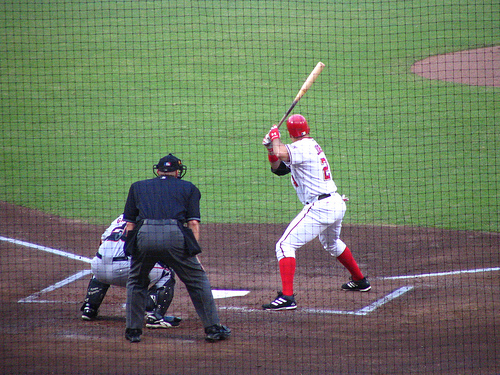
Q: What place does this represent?
A: It represents the field.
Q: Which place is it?
A: It is a field.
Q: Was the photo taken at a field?
A: Yes, it was taken in a field.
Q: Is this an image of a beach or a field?
A: It is showing a field.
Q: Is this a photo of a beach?
A: No, the picture is showing a field.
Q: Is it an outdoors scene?
A: Yes, it is outdoors.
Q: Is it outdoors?
A: Yes, it is outdoors.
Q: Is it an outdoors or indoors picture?
A: It is outdoors.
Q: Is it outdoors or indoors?
A: It is outdoors.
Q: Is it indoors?
A: No, it is outdoors.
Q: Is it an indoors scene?
A: No, it is outdoors.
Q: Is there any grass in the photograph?
A: Yes, there is grass.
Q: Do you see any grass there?
A: Yes, there is grass.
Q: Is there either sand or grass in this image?
A: Yes, there is grass.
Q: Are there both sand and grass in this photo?
A: No, there is grass but no sand.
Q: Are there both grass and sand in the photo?
A: No, there is grass but no sand.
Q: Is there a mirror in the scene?
A: No, there are no mirrors.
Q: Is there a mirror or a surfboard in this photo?
A: No, there are no mirrors or surfboards.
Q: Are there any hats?
A: Yes, there is a hat.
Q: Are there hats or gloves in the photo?
A: Yes, there is a hat.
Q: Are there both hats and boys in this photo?
A: No, there is a hat but no boys.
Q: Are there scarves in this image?
A: No, there are no scarves.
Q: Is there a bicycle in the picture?
A: No, there are no bicycles.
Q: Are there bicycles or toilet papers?
A: No, there are no bicycles or toilet papers.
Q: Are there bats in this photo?
A: Yes, there is a bat.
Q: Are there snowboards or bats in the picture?
A: Yes, there is a bat.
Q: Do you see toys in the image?
A: No, there are no toys.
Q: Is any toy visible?
A: No, there are no toys.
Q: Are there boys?
A: No, there are no boys.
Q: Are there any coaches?
A: No, there are no coaches.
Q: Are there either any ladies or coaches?
A: No, there are no coaches or ladies.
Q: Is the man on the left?
A: Yes, the man is on the left of the image.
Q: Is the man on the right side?
A: No, the man is on the left of the image.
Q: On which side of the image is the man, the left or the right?
A: The man is on the left of the image.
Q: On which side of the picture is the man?
A: The man is on the left of the image.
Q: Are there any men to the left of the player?
A: Yes, there is a man to the left of the player.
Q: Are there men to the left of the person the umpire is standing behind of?
A: Yes, there is a man to the left of the player.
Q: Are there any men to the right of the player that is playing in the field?
A: No, the man is to the left of the player.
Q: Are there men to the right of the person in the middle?
A: No, the man is to the left of the player.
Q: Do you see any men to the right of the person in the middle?
A: No, the man is to the left of the player.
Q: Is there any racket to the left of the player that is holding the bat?
A: No, there is a man to the left of the player.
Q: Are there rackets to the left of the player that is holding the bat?
A: No, there is a man to the left of the player.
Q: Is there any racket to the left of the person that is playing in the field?
A: No, there is a man to the left of the player.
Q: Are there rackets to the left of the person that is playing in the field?
A: No, there is a man to the left of the player.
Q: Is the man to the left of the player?
A: Yes, the man is to the left of the player.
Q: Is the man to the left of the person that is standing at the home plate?
A: Yes, the man is to the left of the player.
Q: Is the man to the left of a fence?
A: No, the man is to the left of the player.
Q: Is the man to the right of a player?
A: No, the man is to the left of a player.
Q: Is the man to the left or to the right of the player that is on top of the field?
A: The man is to the left of the player.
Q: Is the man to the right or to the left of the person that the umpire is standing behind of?
A: The man is to the left of the player.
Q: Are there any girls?
A: No, there are no girls.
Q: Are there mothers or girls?
A: No, there are no girls or mothers.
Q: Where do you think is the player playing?
A: The player is playing in the field.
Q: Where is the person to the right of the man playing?
A: The player is playing in the field.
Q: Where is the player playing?
A: The player is playing in the field.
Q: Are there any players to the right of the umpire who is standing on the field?
A: Yes, there is a player to the right of the umpire.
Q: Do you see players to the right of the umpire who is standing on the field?
A: Yes, there is a player to the right of the umpire.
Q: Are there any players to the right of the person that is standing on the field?
A: Yes, there is a player to the right of the umpire.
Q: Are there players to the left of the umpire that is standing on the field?
A: No, the player is to the right of the umpire.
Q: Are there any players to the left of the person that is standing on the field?
A: No, the player is to the right of the umpire.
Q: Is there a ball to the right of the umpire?
A: No, there is a player to the right of the umpire.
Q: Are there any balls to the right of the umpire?
A: No, there is a player to the right of the umpire.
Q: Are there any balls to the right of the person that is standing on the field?
A: No, there is a player to the right of the umpire.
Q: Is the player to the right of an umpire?
A: Yes, the player is to the right of an umpire.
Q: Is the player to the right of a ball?
A: No, the player is to the right of an umpire.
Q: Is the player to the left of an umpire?
A: No, the player is to the right of an umpire.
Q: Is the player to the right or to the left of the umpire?
A: The player is to the right of the umpire.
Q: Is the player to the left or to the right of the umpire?
A: The player is to the right of the umpire.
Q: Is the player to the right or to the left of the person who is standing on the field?
A: The player is to the right of the umpire.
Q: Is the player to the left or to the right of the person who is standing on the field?
A: The player is to the right of the umpire.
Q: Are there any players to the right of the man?
A: Yes, there is a player to the right of the man.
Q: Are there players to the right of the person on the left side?
A: Yes, there is a player to the right of the man.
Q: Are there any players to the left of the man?
A: No, the player is to the right of the man.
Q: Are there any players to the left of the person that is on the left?
A: No, the player is to the right of the man.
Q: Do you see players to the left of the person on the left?
A: No, the player is to the right of the man.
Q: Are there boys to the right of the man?
A: No, there is a player to the right of the man.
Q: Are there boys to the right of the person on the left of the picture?
A: No, there is a player to the right of the man.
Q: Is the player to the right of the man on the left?
A: Yes, the player is to the right of the man.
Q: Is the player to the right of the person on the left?
A: Yes, the player is to the right of the man.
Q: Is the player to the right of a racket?
A: No, the player is to the right of the man.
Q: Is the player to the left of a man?
A: No, the player is to the right of a man.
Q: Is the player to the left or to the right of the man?
A: The player is to the right of the man.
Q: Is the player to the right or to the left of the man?
A: The player is to the right of the man.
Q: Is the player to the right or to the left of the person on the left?
A: The player is to the right of the man.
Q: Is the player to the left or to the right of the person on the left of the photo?
A: The player is to the right of the man.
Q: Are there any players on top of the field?
A: Yes, there is a player on top of the field.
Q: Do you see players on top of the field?
A: Yes, there is a player on top of the field.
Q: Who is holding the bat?
A: The player is holding the bat.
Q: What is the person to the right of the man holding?
A: The player is holding the bat.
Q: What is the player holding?
A: The player is holding the bat.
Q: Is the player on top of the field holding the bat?
A: Yes, the player is holding the bat.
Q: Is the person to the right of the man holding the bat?
A: Yes, the player is holding the bat.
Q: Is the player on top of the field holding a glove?
A: No, the player is holding the bat.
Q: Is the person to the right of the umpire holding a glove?
A: No, the player is holding the bat.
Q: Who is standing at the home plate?
A: The player is standing at the home plate.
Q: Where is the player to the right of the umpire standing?
A: The player is standing at the home plate.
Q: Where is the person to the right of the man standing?
A: The player is standing at the home plate.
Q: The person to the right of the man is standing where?
A: The player is standing at the home plate.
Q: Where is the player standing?
A: The player is standing at the home plate.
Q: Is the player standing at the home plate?
A: Yes, the player is standing at the home plate.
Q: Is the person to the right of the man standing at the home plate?
A: Yes, the player is standing at the home plate.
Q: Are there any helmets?
A: Yes, there is a helmet.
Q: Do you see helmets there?
A: Yes, there is a helmet.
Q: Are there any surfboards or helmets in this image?
A: Yes, there is a helmet.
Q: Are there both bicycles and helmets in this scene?
A: No, there is a helmet but no bikes.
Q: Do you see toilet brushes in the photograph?
A: No, there are no toilet brushes.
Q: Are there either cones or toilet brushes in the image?
A: No, there are no toilet brushes or cones.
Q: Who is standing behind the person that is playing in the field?
A: The umpire is standing behind the player.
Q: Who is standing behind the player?
A: The umpire is standing behind the player.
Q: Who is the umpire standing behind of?
A: The umpire is standing behind the player.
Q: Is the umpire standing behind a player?
A: Yes, the umpire is standing behind a player.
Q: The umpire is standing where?
A: The umpire is standing on the field.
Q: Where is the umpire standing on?
A: The umpire is standing on the field.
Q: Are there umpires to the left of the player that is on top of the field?
A: Yes, there is an umpire to the left of the player.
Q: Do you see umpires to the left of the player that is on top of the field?
A: Yes, there is an umpire to the left of the player.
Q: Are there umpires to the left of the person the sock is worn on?
A: Yes, there is an umpire to the left of the player.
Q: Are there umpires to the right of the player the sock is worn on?
A: No, the umpire is to the left of the player.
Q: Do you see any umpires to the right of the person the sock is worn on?
A: No, the umpire is to the left of the player.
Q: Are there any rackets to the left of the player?
A: No, there is an umpire to the left of the player.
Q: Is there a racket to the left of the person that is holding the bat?
A: No, there is an umpire to the left of the player.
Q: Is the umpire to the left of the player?
A: Yes, the umpire is to the left of the player.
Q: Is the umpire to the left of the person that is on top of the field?
A: Yes, the umpire is to the left of the player.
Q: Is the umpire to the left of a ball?
A: No, the umpire is to the left of the player.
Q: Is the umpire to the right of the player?
A: No, the umpire is to the left of the player.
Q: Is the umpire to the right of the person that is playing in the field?
A: No, the umpire is to the left of the player.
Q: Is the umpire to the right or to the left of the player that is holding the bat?
A: The umpire is to the left of the player.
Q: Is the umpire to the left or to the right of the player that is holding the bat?
A: The umpire is to the left of the player.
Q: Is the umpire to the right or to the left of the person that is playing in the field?
A: The umpire is to the left of the player.